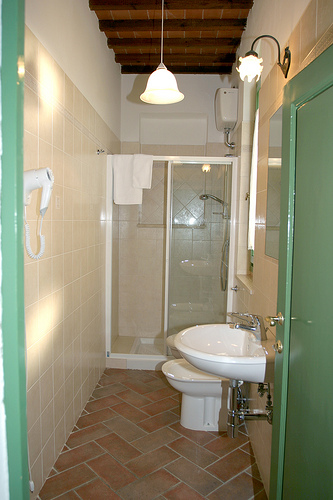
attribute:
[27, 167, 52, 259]
dryer — white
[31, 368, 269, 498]
floor — tiled, brown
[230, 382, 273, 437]
pipes — metal, plumbing 